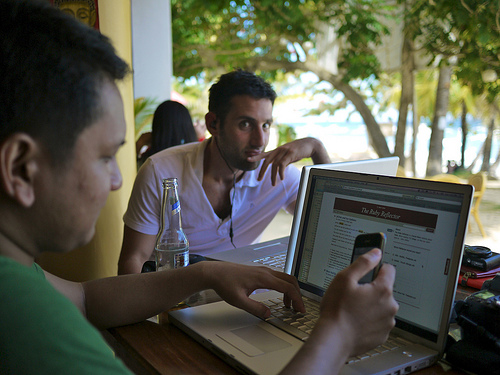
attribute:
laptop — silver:
[171, 167, 474, 372]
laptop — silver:
[202, 155, 401, 272]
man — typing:
[0, 1, 401, 373]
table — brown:
[110, 258, 498, 374]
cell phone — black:
[350, 230, 386, 285]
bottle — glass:
[156, 177, 191, 310]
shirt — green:
[1, 258, 133, 372]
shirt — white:
[124, 137, 301, 248]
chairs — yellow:
[392, 167, 488, 239]